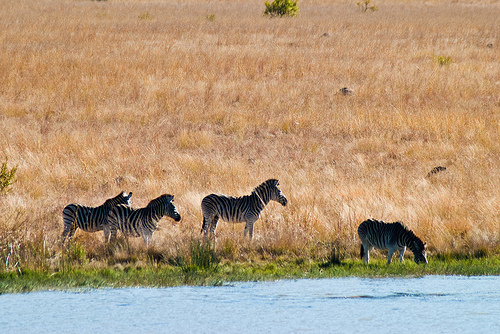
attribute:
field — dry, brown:
[1, 1, 499, 265]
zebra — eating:
[348, 212, 439, 269]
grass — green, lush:
[398, 260, 497, 278]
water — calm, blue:
[1, 272, 499, 333]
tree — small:
[259, 2, 309, 21]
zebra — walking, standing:
[189, 181, 295, 245]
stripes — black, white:
[205, 195, 258, 225]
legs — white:
[353, 242, 407, 266]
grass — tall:
[29, 99, 488, 182]